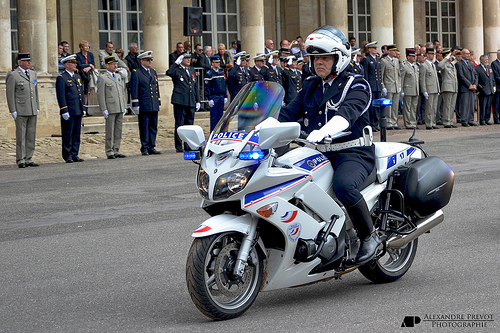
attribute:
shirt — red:
[76, 54, 100, 95]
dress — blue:
[271, 69, 382, 241]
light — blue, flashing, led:
[232, 146, 269, 167]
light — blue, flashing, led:
[178, 145, 200, 168]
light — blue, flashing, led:
[363, 95, 399, 111]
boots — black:
[335, 191, 388, 276]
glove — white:
[299, 112, 352, 152]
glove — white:
[246, 111, 279, 138]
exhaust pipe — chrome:
[364, 197, 456, 261]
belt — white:
[300, 123, 379, 161]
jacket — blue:
[76, 44, 97, 78]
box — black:
[390, 151, 457, 220]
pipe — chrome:
[385, 205, 442, 249]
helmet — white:
[305, 27, 351, 78]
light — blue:
[236, 149, 262, 160]